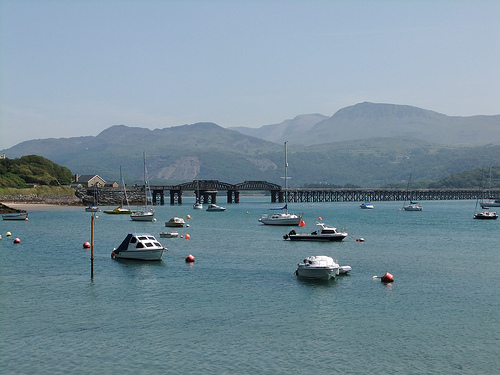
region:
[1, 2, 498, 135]
The sky is blue.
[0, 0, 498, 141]
The sky is hazy.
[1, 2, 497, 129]
The sky is cloudless.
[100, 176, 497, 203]
A bridge spans across the water.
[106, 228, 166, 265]
The boat is drifting in the water.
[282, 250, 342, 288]
The boat is vacant.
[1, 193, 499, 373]
The waters are calm.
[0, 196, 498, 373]
The still water is blue.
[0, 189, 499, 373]
The water is very calm and serene.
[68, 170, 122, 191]
There is a structure on the bank.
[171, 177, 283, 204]
double suspension on bridge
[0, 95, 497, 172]
panoramic mountain view in background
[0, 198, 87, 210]
flat, sandy beach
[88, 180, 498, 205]
long bridge over water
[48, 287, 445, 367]
calm body of water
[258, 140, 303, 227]
sail boat with sail down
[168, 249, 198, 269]
boat anchor buoy and line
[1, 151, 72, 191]
green vegetation on elevated terrain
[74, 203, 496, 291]
several boats in close proximity to one another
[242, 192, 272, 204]
air space clearance for tall boat to pass under bridge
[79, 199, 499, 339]
Boats on the water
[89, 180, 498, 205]
Bridge over water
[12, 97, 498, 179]
Mountains in the distance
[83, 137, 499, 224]
Sail boats with the sales down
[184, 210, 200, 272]
Bowies in the sea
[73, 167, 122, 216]
Waterfront property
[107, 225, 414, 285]
Powerboats all going the same direction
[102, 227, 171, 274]
Large speed boat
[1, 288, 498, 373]
Calm clear water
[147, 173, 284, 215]
Bridge opening for boat traffic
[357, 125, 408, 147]
section of a rugged terrain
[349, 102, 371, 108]
top of a mountain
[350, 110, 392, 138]
slopes of a mountain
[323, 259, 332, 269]
front part of a boat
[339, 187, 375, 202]
section of a bridge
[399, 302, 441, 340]
section of sea water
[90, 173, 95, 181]
part of a house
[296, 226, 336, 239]
a boat on water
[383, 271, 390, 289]
a floater on water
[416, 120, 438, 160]
part of a hilly forest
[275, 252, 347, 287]
a white boat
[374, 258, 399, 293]
a red bouy in water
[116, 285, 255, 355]
A body of water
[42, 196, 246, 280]
Many boats are in the water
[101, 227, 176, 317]
A leisure boat is in the water and it is white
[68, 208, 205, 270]
Many red bouys and boats in water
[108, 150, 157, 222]
Two sail boats are in the water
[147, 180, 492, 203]
A bridge that crosses a body of water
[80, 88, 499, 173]
Many mountains in the background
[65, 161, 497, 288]
Bridge and many boats